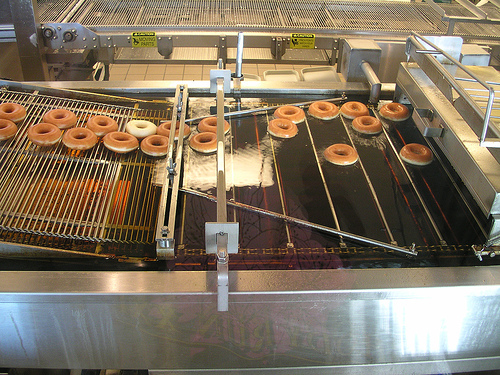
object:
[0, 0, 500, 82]
machine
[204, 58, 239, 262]
rod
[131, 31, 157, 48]
warning label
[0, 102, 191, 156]
donut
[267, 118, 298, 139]
donut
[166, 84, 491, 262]
belt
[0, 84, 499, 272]
grease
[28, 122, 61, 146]
donut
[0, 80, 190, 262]
belt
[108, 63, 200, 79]
ground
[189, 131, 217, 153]
donut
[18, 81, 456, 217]
donut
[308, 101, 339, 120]
donut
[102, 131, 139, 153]
donut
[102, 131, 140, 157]
center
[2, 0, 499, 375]
equipment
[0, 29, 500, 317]
machinery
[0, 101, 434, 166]
donuts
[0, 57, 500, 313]
conveyor belt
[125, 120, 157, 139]
donut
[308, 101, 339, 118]
top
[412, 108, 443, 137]
handle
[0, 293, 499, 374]
reflection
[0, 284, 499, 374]
surface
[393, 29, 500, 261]
mechanism